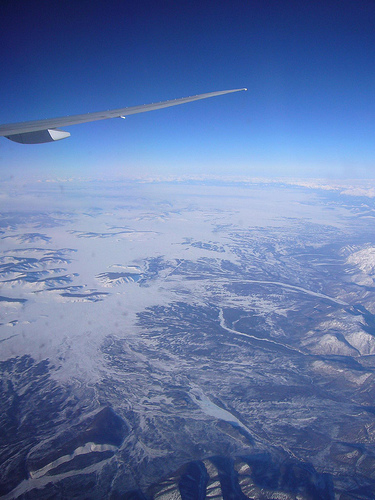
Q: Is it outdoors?
A: Yes, it is outdoors.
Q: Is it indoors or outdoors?
A: It is outdoors.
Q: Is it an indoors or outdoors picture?
A: It is outdoors.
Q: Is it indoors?
A: No, it is outdoors.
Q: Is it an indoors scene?
A: No, it is outdoors.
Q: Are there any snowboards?
A: No, there are no snowboards.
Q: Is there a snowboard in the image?
A: No, there are no snowboards.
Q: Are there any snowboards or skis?
A: No, there are no snowboards or skis.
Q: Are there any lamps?
A: No, there are no lamps.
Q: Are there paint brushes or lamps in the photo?
A: No, there are no lamps or paint brushes.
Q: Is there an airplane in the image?
A: Yes, there is an airplane.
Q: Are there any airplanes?
A: Yes, there is an airplane.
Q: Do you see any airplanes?
A: Yes, there is an airplane.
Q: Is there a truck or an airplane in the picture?
A: Yes, there is an airplane.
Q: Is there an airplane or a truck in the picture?
A: Yes, there is an airplane.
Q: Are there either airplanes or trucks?
A: Yes, there is an airplane.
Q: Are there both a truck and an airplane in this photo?
A: No, there is an airplane but no trucks.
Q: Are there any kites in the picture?
A: No, there are no kites.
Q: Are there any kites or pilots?
A: No, there are no kites or pilots.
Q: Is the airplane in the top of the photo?
A: Yes, the airplane is in the top of the image.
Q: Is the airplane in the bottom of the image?
A: No, the airplane is in the top of the image.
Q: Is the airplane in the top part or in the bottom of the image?
A: The airplane is in the top of the image.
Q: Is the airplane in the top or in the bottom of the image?
A: The airplane is in the top of the image.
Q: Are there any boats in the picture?
A: No, there are no boats.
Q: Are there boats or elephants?
A: No, there are no boats or elephants.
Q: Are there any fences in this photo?
A: No, there are no fences.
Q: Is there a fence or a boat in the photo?
A: No, there are no fences or boats.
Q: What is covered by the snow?
A: The mountains are covered by the snow.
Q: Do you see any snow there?
A: Yes, there is snow.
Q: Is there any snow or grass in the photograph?
A: Yes, there is snow.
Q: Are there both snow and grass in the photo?
A: No, there is snow but no grass.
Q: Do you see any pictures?
A: No, there are no pictures.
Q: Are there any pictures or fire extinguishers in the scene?
A: No, there are no pictures or fire extinguishers.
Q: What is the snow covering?
A: The snow is covering the mountains.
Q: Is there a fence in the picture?
A: No, there are no fences.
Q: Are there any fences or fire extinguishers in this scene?
A: No, there are no fences or fire extinguishers.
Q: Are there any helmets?
A: No, there are no helmets.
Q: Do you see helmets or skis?
A: No, there are no helmets or skis.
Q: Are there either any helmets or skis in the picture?
A: No, there are no helmets or skis.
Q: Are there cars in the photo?
A: No, there are no cars.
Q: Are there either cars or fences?
A: No, there are no cars or fences.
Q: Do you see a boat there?
A: No, there are no boats.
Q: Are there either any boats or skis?
A: No, there are no boats or skis.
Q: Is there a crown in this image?
A: No, there are no crowns.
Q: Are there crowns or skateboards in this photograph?
A: No, there are no crowns or skateboards.